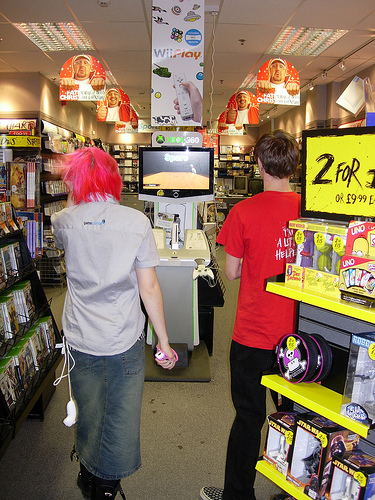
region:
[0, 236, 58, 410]
video games stacked on black shelves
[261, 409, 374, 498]
Star Wars toys on a yellow shelf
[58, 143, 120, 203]
a girl with red bright hair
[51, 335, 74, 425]
a white controller and wires hanging from girl's hips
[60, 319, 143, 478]
girl wearing a long jeans skirt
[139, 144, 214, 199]
a black TV in a store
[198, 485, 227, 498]
man wearing white and black checkered shoes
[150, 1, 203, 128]
advertisement hanging from the ceiling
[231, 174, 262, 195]
old TVs on a counter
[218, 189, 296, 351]
man wearing a red shirt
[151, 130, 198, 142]
xbox 360 display sign on tv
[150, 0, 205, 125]
wii banner hanging from ceiling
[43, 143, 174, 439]
kid playing video game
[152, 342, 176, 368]
wii controller in kids's hand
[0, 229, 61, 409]
xbox 360 video game display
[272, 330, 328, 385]
skull carrying case for cd's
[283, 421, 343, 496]
star wars play figure on shelf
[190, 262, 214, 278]
xbox 360 controller on display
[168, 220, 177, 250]
wii console video game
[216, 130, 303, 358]
kid in red shirt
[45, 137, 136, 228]
person with red hair plays nintendo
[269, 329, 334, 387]
black and pink circle purse sitting on the shelf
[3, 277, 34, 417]
video games line the shelves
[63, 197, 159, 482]
person is wearing two different blue clothing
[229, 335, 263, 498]
person is wearing black pants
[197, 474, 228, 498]
person is wearing checkered shoes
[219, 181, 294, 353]
person is wearing a red shirt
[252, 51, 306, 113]
orange white and tan poster hangs from ceiling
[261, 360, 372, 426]
shelf in the store is yellow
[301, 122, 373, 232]
yellow and black sign hangs above the shelves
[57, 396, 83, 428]
a white game controller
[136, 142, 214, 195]
a small t.v. screen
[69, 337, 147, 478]
a woman's blue jean skirt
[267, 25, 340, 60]
a ceiling light fixture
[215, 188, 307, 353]
part of a boy's red shirt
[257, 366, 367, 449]
part of a yellow shelf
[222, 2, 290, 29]
a white ceiling tile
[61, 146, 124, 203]
a pink wig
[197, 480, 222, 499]
the shoe of a boy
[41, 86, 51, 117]
a light reflection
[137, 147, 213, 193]
A black framed television.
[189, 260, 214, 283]
An xbox white controller.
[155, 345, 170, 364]
A white wii controller.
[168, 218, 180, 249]
A white wii game console.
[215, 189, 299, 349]
A red short sleeved shirt.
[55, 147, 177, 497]
A girl playing the wii.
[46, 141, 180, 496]
A girl with pink hair.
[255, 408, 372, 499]
Boxed Star Wars figurines.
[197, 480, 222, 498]
A checkered shoe.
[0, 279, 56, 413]
Xbox video games.